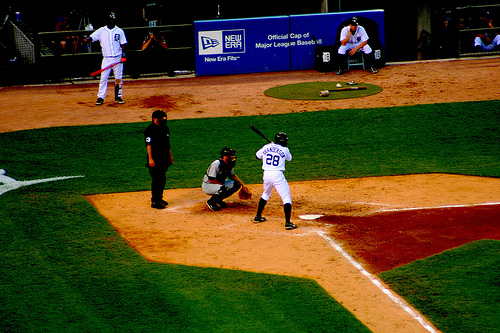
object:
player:
[253, 132, 297, 230]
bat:
[249, 124, 272, 144]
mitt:
[238, 187, 253, 199]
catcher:
[201, 147, 251, 212]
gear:
[216, 159, 233, 186]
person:
[334, 18, 381, 75]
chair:
[346, 53, 367, 72]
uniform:
[82, 24, 129, 98]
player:
[81, 17, 127, 106]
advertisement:
[194, 10, 387, 76]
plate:
[298, 212, 323, 220]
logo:
[113, 34, 121, 42]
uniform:
[255, 144, 292, 207]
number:
[265, 153, 280, 165]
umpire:
[144, 109, 174, 210]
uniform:
[201, 158, 236, 194]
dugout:
[32, 1, 498, 84]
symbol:
[0, 168, 85, 196]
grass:
[0, 190, 368, 333]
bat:
[90, 59, 124, 77]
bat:
[326, 86, 366, 92]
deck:
[261, 80, 378, 101]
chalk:
[315, 225, 436, 333]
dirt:
[314, 204, 500, 275]